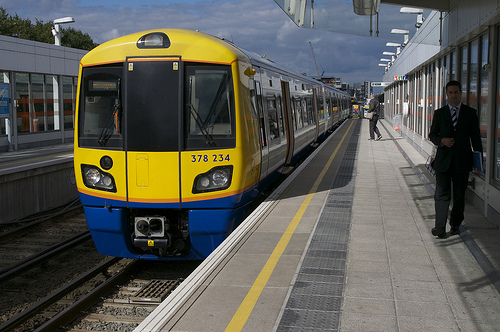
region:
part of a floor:
[359, 245, 396, 292]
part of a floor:
[370, 241, 383, 275]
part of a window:
[178, 83, 200, 107]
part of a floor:
[377, 247, 411, 298]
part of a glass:
[188, 78, 206, 116]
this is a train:
[57, 37, 398, 254]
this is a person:
[421, 56, 483, 242]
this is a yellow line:
[221, 292, 257, 326]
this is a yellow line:
[238, 211, 283, 309]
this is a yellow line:
[286, 208, 321, 250]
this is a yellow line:
[298, 178, 325, 202]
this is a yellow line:
[329, 127, 351, 161]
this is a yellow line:
[230, 278, 260, 320]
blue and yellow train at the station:
[72, 33, 354, 258]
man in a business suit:
[426, 81, 481, 241]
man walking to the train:
[360, 93, 382, 139]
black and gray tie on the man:
[450, 105, 457, 129]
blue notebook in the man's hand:
[469, 150, 483, 174]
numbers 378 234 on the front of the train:
[189, 149, 231, 165]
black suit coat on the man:
[430, 105, 482, 172]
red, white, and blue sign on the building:
[392, 73, 406, 83]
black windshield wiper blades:
[97, 77, 211, 146]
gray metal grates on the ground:
[261, 116, 363, 331]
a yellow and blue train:
[78, 35, 337, 248]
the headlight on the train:
[193, 170, 233, 188]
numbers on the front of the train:
[187, 152, 238, 164]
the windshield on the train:
[83, 65, 233, 143]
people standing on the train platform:
[361, 78, 490, 227]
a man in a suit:
[420, 76, 484, 238]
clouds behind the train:
[218, 23, 391, 54]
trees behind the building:
[4, 8, 110, 43]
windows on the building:
[9, 69, 74, 125]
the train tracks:
[5, 237, 118, 327]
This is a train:
[74, 28, 361, 251]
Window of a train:
[123, 49, 185, 154]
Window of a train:
[183, 60, 239, 160]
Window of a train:
[76, 62, 128, 156]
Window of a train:
[246, 71, 276, 171]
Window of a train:
[30, 65, 48, 140]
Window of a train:
[12, 66, 35, 137]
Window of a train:
[43, 71, 61, 136]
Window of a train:
[59, 68, 82, 143]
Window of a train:
[264, 77, 284, 149]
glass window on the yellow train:
[76, 68, 118, 138]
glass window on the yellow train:
[126, 61, 178, 146]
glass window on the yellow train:
[185, 67, 230, 142]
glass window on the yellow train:
[251, 75, 267, 140]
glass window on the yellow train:
[267, 92, 277, 139]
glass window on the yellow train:
[292, 82, 300, 127]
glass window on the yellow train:
[298, 82, 308, 129]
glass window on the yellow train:
[303, 82, 310, 124]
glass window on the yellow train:
[315, 89, 324, 122]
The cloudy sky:
[6, 0, 402, 91]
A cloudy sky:
[3, 1, 436, 111]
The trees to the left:
[0, 8, 110, 75]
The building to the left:
[1, 30, 107, 144]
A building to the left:
[1, 28, 113, 153]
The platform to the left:
[0, 136, 92, 183]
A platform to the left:
[0, 141, 86, 172]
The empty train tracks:
[9, 187, 98, 277]